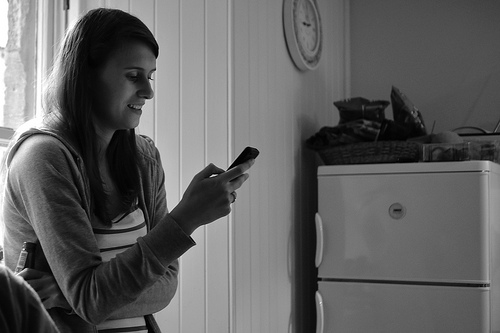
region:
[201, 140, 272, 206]
A handheld communication device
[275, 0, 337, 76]
An apparatus to tell time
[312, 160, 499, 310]
An electric ice box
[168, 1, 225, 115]
Vertical grooved paneling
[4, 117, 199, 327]
A light grey hooded sweat shirt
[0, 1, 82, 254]
A window to the outside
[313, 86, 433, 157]
Snack food in a basket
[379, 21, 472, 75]
A painted wall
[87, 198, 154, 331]
A shirt with horizontal stripes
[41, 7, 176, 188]
A woman stands here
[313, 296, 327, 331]
White handle of the refrigerator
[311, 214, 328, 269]
White handle of the freezer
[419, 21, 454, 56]
White wall in the room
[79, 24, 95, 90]
Dark hair of the girl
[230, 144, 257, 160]
Black cellphone of the girl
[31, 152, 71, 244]
Gray sweater of the female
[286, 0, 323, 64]
Clock on the wall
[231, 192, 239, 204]
Ring on the girl's finger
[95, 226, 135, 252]
Striped shirt of the girl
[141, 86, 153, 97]
Nose of the girl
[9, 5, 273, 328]
woman on cell phone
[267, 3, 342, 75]
clock on a wall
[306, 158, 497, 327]
refrigerator in a kitchen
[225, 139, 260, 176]
cell phone in woman's hand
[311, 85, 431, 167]
basket of chips on refrigerator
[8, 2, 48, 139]
window in a kitchen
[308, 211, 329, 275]
handle on a freezer door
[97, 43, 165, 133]
face of a woman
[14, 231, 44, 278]
bottle in woman's hand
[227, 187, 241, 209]
ring on woman's finger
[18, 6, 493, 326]
the photograph is black and white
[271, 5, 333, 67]
the clock on the wall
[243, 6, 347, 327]
the wall has panelling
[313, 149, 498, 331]
the small refrigerator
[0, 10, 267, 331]
the woman on the phone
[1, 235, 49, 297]
the bottle in the hand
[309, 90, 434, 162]
the chips in the basket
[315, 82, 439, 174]
the basket above the refrigerator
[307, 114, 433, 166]
the basket is straw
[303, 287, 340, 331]
the handle of the refrigerator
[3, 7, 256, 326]
a person looking at her cellphone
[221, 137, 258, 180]
a cellphone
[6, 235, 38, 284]
a bottle of drink the lady is holding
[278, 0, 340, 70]
a clock on the wall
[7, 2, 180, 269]
a woman with long hair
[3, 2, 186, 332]
a lady in front of the window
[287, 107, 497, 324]
a white refrigerator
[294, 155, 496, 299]
the freezer top of a refrigerator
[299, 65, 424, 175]
a tray of packed goodies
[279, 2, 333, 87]
a white wall clock